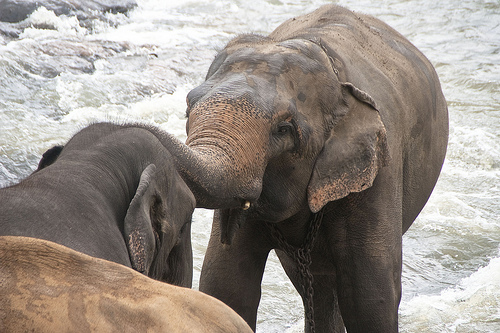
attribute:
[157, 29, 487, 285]
elephant — large, grey, big, fat, old, dirty, standing, brown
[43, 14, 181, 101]
ground — white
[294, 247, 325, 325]
chain — silver, old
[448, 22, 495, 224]
water — white, clear